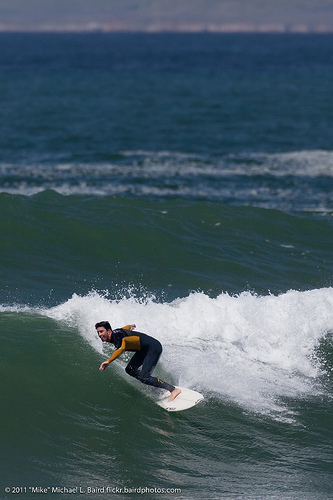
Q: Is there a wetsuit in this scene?
A: Yes, there is a wetsuit.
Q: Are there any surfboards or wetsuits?
A: Yes, there is a wetsuit.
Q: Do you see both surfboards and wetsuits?
A: Yes, there are both a wetsuit and a surfboard.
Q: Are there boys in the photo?
A: No, there are no boys.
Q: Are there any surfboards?
A: Yes, there is a surfboard.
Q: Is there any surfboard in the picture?
A: Yes, there is a surfboard.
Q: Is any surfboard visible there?
A: Yes, there is a surfboard.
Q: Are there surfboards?
A: Yes, there is a surfboard.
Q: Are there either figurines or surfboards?
A: Yes, there is a surfboard.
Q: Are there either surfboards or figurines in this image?
A: Yes, there is a surfboard.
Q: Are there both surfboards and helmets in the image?
A: No, there is a surfboard but no helmets.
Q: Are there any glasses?
A: No, there are no glasses.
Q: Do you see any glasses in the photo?
A: No, there are no glasses.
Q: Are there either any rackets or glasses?
A: No, there are no glasses or rackets.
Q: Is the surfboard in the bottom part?
A: Yes, the surfboard is in the bottom of the image.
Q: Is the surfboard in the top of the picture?
A: No, the surfboard is in the bottom of the image.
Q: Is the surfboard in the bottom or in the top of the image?
A: The surfboard is in the bottom of the image.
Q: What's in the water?
A: The surfboard is in the water.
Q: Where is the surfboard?
A: The surfboard is in the water.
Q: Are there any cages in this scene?
A: No, there are no cages.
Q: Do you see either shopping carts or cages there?
A: No, there are no cages or shopping carts.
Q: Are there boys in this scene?
A: No, there are no boys.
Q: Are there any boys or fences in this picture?
A: No, there are no boys or fences.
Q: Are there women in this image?
A: No, there are no women.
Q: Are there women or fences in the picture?
A: No, there are no women or fences.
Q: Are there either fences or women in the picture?
A: No, there are no women or fences.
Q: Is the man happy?
A: Yes, the man is happy.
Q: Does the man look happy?
A: Yes, the man is happy.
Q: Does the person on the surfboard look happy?
A: Yes, the man is happy.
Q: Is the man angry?
A: No, the man is happy.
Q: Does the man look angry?
A: No, the man is happy.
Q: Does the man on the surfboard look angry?
A: No, the man is happy.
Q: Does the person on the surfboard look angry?
A: No, the man is happy.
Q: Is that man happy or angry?
A: The man is happy.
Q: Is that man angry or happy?
A: The man is happy.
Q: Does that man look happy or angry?
A: The man is happy.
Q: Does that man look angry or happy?
A: The man is happy.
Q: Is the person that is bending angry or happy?
A: The man is happy.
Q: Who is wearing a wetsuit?
A: The man is wearing a wetsuit.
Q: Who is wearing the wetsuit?
A: The man is wearing a wetsuit.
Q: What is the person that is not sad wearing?
A: The man is wearing a wet suit.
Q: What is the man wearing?
A: The man is wearing a wet suit.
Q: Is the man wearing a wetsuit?
A: Yes, the man is wearing a wetsuit.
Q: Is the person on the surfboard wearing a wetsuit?
A: Yes, the man is wearing a wetsuit.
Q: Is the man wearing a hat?
A: No, the man is wearing a wetsuit.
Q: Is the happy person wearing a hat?
A: No, the man is wearing a wetsuit.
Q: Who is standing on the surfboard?
A: The man is standing on the surfboard.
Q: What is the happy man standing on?
A: The man is standing on the surfboard.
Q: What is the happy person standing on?
A: The man is standing on the surfboard.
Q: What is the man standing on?
A: The man is standing on the surfboard.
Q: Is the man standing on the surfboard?
A: Yes, the man is standing on the surfboard.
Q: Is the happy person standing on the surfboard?
A: Yes, the man is standing on the surfboard.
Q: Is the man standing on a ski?
A: No, the man is standing on the surfboard.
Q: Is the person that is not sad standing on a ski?
A: No, the man is standing on the surfboard.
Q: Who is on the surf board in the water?
A: The man is on the surfboard.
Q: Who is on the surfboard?
A: The man is on the surfboard.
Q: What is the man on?
A: The man is on the surf board.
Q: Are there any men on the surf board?
A: Yes, there is a man on the surf board.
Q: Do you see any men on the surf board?
A: Yes, there is a man on the surf board.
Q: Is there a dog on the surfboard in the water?
A: No, there is a man on the surfboard.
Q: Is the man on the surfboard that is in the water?
A: Yes, the man is on the surfboard.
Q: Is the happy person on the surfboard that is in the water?
A: Yes, the man is on the surfboard.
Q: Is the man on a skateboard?
A: No, the man is on the surfboard.